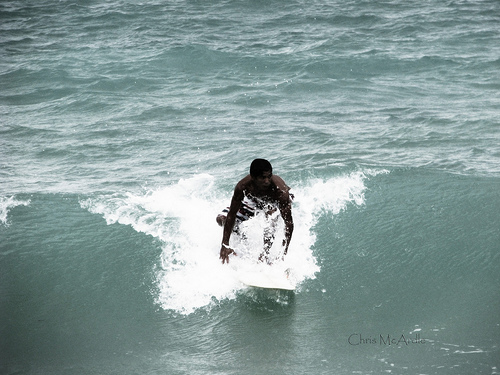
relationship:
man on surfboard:
[217, 157, 296, 263] [228, 243, 291, 290]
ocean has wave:
[1, 1, 499, 374] [0, 169, 494, 298]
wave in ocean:
[0, 169, 494, 298] [1, 1, 499, 374]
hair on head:
[251, 159, 269, 176] [249, 159, 272, 191]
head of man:
[249, 159, 272, 191] [217, 157, 296, 263]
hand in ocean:
[217, 247, 232, 264] [1, 1, 499, 374]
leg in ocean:
[219, 200, 257, 246] [1, 1, 499, 374]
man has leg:
[217, 157, 296, 263] [219, 200, 257, 246]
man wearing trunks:
[217, 157, 296, 263] [222, 194, 294, 234]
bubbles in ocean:
[275, 288, 326, 306] [1, 1, 499, 374]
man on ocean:
[217, 157, 296, 263] [1, 1, 499, 374]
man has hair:
[217, 157, 296, 263] [251, 159, 269, 176]